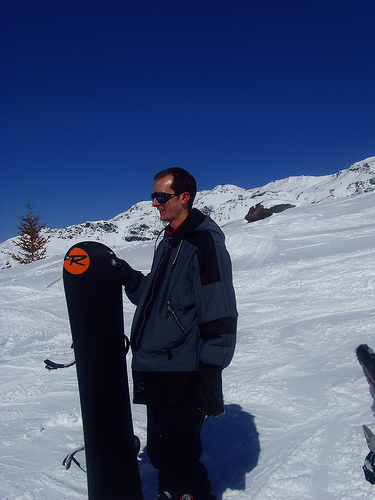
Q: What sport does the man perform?
A: Snowboarding.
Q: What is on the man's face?
A: Sunglasses.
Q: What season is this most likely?
A: Winter.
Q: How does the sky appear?
A: Very blue and clear.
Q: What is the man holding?
A: A snowboard.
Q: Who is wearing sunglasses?
A: A man.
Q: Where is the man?
A: On ski slope.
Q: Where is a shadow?
A: On the snow.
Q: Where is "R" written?
A: On the snowboard.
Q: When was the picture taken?
A: During the daytime.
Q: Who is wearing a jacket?
A: The snowboarder.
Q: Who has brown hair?
A: Snowboarder.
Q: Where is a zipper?
A: On the jacket.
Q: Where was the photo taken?
A: On a snowy mountain.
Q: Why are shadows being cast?
A: Sun shining.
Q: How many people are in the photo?
A: One.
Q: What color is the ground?
A: White.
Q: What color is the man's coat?
A: Grey and black.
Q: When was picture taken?
A: Daytime.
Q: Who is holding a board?
A: A man.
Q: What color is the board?
A: Black.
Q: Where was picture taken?
A: On a ski slope.